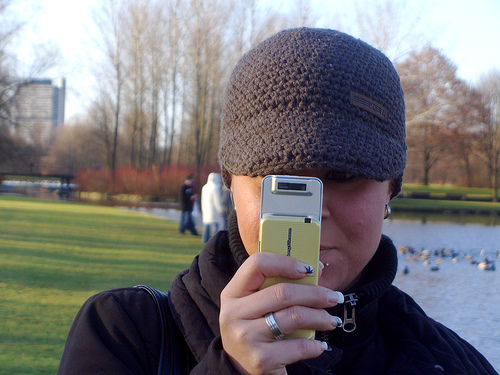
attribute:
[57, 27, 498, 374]
woman — taking a picture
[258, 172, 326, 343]
phone — yellow, gray, silver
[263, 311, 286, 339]
ring — silver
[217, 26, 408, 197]
cap — brown, knit, knitted, crocheted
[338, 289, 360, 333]
zipper — silver, dark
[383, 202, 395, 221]
earring — silver, small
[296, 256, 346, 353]
nails — long, painted, black, white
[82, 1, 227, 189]
trees — bare, tall, thin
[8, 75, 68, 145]
building — tall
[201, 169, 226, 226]
hoodie — white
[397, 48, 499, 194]
trees — tall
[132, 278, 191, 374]
strap — black, leather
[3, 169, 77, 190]
bridge — small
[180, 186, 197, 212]
shirt — black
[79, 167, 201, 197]
bushes — red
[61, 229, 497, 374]
jacket — black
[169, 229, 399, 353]
collar — pulled up